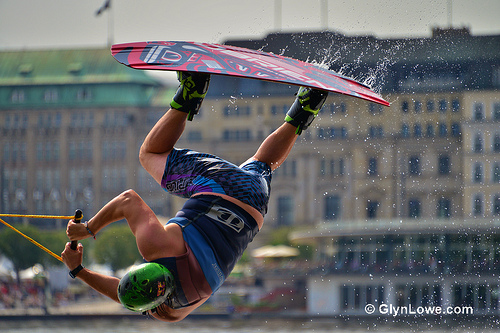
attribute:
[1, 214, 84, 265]
rope — yellow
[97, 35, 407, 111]
board — water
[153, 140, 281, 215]
swim trunks — striped, blue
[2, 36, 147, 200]
building — large, stone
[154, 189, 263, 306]
shirt — sleeveless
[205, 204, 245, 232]
logo — athletic, company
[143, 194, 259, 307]
shirt — blue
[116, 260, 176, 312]
helmet — green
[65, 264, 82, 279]
watch — black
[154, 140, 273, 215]
shorts — blue, black, purple 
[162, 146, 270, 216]
swim trunks — black, purple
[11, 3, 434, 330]
person — wakeboarding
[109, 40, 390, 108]
wake board — red, black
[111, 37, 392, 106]
water board — red, blue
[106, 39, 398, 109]
board — kite surfing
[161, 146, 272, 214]
shorts — blue, black, checkered, swim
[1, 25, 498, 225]
stone building — large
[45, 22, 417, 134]
water board — upside down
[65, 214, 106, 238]
bracelet — small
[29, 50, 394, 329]
bracelet — small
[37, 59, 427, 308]
man — filpping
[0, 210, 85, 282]
rope — yellow, tow, connected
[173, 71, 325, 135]
boots — attached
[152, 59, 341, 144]
shoes — green, black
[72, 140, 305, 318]
man — holding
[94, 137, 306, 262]
man — wearing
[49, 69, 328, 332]
man — wearing